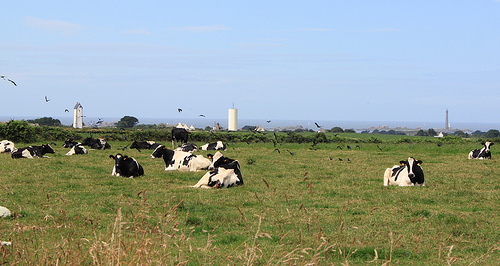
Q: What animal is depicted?
A: Cow.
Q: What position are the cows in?
A: Reclined.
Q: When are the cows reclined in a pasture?
A: On a sunny day.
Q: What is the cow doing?
A: Sitting.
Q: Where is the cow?
A: In the field.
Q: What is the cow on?
A: Grass.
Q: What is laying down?
A: Cows.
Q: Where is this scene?
A: A field.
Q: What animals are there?
A: Cows.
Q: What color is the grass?
A: Green.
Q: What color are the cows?
A: Black and white.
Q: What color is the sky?
A: Blue.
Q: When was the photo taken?
A: Daytime.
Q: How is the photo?
A: Clear.